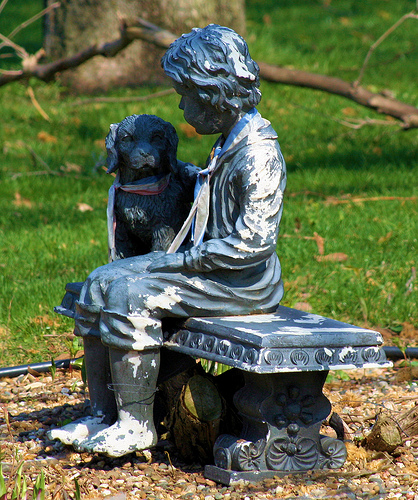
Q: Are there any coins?
A: No, there are no coins.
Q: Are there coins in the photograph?
A: No, there are no coins.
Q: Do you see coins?
A: No, there are no coins.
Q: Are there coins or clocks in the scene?
A: No, there are no coins or clocks.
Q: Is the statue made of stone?
A: Yes, the statue is made of stone.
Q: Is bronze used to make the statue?
A: No, the statue is made of stone.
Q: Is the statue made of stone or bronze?
A: The statue is made of stone.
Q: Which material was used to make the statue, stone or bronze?
A: The statue is made of stone.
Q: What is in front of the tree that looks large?
A: The statue is in front of the tree.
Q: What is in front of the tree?
A: The statue is in front of the tree.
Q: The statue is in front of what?
A: The statue is in front of the tree.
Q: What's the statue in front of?
A: The statue is in front of the tree.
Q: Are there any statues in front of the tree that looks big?
A: Yes, there is a statue in front of the tree.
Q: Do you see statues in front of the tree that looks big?
A: Yes, there is a statue in front of the tree.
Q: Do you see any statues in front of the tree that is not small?
A: Yes, there is a statue in front of the tree.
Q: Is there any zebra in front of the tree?
A: No, there is a statue in front of the tree.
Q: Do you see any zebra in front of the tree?
A: No, there is a statue in front of the tree.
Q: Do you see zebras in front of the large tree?
A: No, there is a statue in front of the tree.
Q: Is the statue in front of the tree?
A: Yes, the statue is in front of the tree.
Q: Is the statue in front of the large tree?
A: Yes, the statue is in front of the tree.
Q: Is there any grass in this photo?
A: Yes, there is grass.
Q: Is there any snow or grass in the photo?
A: Yes, there is grass.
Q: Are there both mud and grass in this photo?
A: No, there is grass but no mud.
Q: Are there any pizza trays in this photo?
A: No, there are no pizza trays.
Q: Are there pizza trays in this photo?
A: No, there are no pizza trays.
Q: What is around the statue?
A: The grass is around the statue.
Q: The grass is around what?
A: The grass is around the statue.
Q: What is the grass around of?
A: The grass is around the statue.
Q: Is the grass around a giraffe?
A: No, the grass is around a statue.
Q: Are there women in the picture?
A: No, there are no women.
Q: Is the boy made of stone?
A: Yes, the boy is made of stone.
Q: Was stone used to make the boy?
A: Yes, the boy is made of stone.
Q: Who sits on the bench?
A: The boy sits on the bench.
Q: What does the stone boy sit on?
A: The boy sits on the bench.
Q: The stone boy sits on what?
A: The boy sits on the bench.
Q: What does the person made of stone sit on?
A: The boy sits on the bench.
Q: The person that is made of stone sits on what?
A: The boy sits on the bench.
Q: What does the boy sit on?
A: The boy sits on the bench.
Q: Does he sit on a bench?
A: Yes, the boy sits on a bench.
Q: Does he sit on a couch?
A: No, the boy sits on a bench.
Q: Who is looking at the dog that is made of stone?
A: The boy is looking at the dog.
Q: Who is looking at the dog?
A: The boy is looking at the dog.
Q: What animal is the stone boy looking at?
A: The boy is looking at the dog.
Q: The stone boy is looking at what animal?
A: The boy is looking at the dog.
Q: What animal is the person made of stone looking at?
A: The boy is looking at the dog.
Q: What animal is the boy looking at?
A: The boy is looking at the dog.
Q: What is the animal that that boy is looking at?
A: The animal is a dog.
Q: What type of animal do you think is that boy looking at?
A: The boy is looking at the dog.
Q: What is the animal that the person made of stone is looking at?
A: The animal is a dog.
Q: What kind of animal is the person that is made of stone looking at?
A: The boy is looking at the dog.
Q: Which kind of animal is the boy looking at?
A: The boy is looking at the dog.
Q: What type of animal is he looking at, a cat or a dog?
A: The boy is looking at a dog.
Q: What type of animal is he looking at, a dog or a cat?
A: The boy is looking at a dog.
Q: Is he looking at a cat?
A: No, the boy is looking at the dog.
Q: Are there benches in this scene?
A: Yes, there is a bench.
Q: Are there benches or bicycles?
A: Yes, there is a bench.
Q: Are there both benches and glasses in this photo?
A: No, there is a bench but no glasses.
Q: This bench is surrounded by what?
A: The bench is surrounded by the rocks.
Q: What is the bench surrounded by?
A: The bench is surrounded by the rocks.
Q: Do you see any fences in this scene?
A: No, there are no fences.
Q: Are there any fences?
A: No, there are no fences.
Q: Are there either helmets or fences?
A: No, there are no fences or helmets.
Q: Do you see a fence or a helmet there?
A: No, there are no fences or helmets.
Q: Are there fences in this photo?
A: No, there are no fences.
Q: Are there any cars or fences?
A: No, there are no fences or cars.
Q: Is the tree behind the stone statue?
A: Yes, the tree is behind the statue.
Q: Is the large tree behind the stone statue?
A: Yes, the tree is behind the statue.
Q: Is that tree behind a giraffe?
A: No, the tree is behind the statue.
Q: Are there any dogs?
A: Yes, there is a dog.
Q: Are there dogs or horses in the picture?
A: Yes, there is a dog.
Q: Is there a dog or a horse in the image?
A: Yes, there is a dog.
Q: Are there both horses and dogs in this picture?
A: No, there is a dog but no horses.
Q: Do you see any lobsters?
A: No, there are no lobsters.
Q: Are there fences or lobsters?
A: No, there are no lobsters or fences.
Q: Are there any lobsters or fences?
A: No, there are no lobsters or fences.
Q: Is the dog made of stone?
A: Yes, the dog is made of stone.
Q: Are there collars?
A: Yes, there is a collar.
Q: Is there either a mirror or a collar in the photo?
A: Yes, there is a collar.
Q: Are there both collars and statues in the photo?
A: Yes, there are both a collar and a statue.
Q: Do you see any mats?
A: No, there are no mats.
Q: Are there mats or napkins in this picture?
A: No, there are no mats or napkins.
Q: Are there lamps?
A: No, there are no lamps.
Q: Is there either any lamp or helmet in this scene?
A: No, there are no lamps or helmets.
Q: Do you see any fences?
A: No, there are no fences.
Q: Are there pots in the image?
A: No, there are no pots.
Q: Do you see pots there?
A: No, there are no pots.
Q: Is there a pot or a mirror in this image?
A: No, there are no pots or mirrors.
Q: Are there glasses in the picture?
A: No, there are no glasses.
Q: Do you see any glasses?
A: No, there are no glasses.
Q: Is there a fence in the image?
A: No, there are no fences.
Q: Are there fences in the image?
A: No, there are no fences.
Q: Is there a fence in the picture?
A: No, there are no fences.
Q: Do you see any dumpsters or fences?
A: No, there are no fences or dumpsters.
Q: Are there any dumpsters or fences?
A: No, there are no fences or dumpsters.